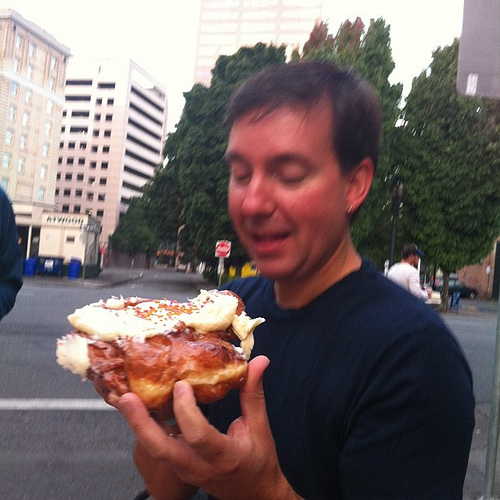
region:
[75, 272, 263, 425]
man is holding a food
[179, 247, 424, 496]
the shirt is black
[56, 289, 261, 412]
the pastry is brown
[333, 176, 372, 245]
man is wearing an earring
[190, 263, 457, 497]
man is wearing a shirt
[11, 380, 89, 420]
the line is white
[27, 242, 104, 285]
the trash bin is blue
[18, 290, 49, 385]
the ground is gray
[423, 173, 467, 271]
the leaves are green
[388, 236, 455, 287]
man is wearing a cap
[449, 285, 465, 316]
mailbox on right side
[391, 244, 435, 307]
man in white shirt on right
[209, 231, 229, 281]
stop sign in cneter of background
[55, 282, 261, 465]
large sandwich in man's hand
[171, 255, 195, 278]
silver car in background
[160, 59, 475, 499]
man in black shirt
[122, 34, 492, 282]
trees in background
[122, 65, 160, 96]
banner on side of building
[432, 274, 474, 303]
car parked next to building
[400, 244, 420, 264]
baseball cap on man with white shirt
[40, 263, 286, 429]
a huge donut with frosting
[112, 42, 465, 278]
green fluffy trees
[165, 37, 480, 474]
a man with a blue shirt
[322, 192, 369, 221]
a silver small earring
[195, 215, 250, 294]
a red and white sign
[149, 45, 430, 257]
a man is smiling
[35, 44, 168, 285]
a tall white building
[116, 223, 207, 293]
an empty street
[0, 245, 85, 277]
2 blue garbage cans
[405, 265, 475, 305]
1 parked car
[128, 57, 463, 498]
man holding doughnut in street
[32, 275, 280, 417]
doughnut is brown and white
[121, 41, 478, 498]
man in blue shirt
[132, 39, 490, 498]
man in street with eyes closed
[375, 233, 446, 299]
white man in background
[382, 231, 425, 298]
man in white shirt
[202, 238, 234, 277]
red stop sign by tree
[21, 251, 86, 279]
blue trash cans by white building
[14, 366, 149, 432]
white line on road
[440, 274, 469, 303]
black car by brick building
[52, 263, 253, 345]
the cheese is yellow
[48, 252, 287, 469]
man is holding a pastry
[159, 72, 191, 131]
the sky is white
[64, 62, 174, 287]
the building is white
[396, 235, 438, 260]
the cap is brown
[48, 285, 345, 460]
the pastry is brown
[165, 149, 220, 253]
the trees are green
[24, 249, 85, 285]
trash bins are blue